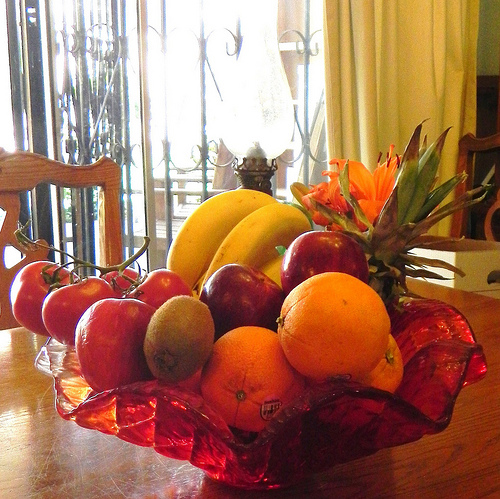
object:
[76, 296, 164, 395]
apple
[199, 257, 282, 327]
apple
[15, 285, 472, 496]
bowl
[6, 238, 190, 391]
tomatoes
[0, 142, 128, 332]
chair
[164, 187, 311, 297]
bananas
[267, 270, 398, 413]
orange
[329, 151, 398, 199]
flower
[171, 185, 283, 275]
fruit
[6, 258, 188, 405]
vegetables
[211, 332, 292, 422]
orange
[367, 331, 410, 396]
orange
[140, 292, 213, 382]
kiwi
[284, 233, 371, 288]
apple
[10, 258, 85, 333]
tomatoes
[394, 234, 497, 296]
box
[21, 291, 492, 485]
dish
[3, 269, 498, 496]
table